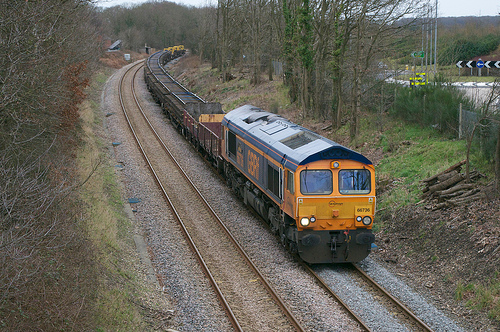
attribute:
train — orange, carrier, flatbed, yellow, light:
[144, 41, 375, 265]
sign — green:
[413, 48, 431, 61]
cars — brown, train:
[146, 52, 225, 167]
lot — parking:
[386, 76, 499, 111]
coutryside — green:
[366, 110, 471, 202]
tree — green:
[279, 6, 349, 127]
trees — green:
[207, 1, 437, 150]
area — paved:
[463, 87, 499, 107]